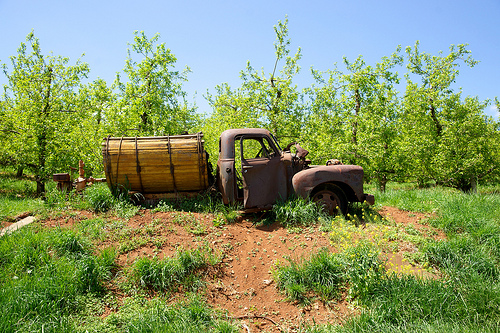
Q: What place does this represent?
A: It represents the field.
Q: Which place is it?
A: It is a field.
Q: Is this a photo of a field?
A: Yes, it is showing a field.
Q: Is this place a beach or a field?
A: It is a field.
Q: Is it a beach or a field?
A: It is a field.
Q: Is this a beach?
A: No, it is a field.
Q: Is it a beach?
A: No, it is a field.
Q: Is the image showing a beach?
A: No, the picture is showing a field.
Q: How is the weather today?
A: It is cloudless.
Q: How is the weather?
A: It is cloudless.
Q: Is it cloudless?
A: Yes, it is cloudless.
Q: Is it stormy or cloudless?
A: It is cloudless.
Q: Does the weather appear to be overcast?
A: No, it is cloudless.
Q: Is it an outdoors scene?
A: Yes, it is outdoors.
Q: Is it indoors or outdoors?
A: It is outdoors.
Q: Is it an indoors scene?
A: No, it is outdoors.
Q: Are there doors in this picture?
A: Yes, there is a door.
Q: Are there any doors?
A: Yes, there is a door.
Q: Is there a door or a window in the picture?
A: Yes, there is a door.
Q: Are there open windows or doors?
A: Yes, there is an open door.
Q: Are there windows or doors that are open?
A: Yes, the door is open.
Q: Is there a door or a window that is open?
A: Yes, the door is open.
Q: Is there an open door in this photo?
A: Yes, there is an open door.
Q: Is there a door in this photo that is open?
A: Yes, there is a door that is open.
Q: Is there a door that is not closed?
A: Yes, there is a open door.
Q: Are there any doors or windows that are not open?
A: No, there is a door but it is open.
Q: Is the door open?
A: Yes, the door is open.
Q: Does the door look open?
A: Yes, the door is open.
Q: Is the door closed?
A: No, the door is open.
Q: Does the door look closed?
A: No, the door is open.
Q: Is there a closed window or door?
A: No, there is a door but it is open.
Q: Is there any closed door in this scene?
A: No, there is a door but it is open.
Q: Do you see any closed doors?
A: No, there is a door but it is open.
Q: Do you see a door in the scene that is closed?
A: No, there is a door but it is open.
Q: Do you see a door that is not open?
A: No, there is a door but it is open.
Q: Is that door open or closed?
A: The door is open.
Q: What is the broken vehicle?
A: The vehicle is a car.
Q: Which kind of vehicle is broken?
A: The vehicle is a car.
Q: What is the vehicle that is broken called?
A: The vehicle is a car.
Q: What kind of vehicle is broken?
A: The vehicle is a car.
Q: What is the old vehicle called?
A: The vehicle is a car.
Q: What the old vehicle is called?
A: The vehicle is a car.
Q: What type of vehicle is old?
A: The vehicle is a car.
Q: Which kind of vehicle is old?
A: The vehicle is a car.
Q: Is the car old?
A: Yes, the car is old.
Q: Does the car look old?
A: Yes, the car is old.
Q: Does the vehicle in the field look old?
A: Yes, the car is old.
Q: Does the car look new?
A: No, the car is old.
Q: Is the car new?
A: No, the car is old.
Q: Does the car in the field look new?
A: No, the car is old.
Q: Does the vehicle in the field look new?
A: No, the car is old.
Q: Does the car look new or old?
A: The car is old.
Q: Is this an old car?
A: Yes, this is an old car.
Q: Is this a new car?
A: No, this is an old car.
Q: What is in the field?
A: The car is in the field.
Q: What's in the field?
A: The car is in the field.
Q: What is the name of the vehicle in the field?
A: The vehicle is a car.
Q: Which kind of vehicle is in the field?
A: The vehicle is a car.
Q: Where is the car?
A: The car is in the field.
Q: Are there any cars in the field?
A: Yes, there is a car in the field.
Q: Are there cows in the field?
A: No, there is a car in the field.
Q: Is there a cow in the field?
A: No, there is a car in the field.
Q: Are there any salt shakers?
A: No, there are no salt shakers.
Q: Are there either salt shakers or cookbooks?
A: No, there are no salt shakers or cookbooks.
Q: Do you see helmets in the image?
A: No, there are no helmets.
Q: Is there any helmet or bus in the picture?
A: No, there are no helmets or buses.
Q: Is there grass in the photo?
A: Yes, there is grass.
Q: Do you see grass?
A: Yes, there is grass.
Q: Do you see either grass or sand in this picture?
A: Yes, there is grass.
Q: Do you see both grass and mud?
A: No, there is grass but no mud.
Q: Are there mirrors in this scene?
A: No, there are no mirrors.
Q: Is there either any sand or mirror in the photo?
A: No, there are no mirrors or sand.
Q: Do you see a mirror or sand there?
A: No, there are no mirrors or sand.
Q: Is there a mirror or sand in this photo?
A: No, there are no mirrors or sand.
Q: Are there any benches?
A: No, there are no benches.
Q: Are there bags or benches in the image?
A: No, there are no benches or bags.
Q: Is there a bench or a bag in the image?
A: No, there are no benches or bags.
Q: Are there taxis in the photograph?
A: Yes, there is a taxi.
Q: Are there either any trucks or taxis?
A: Yes, there is a taxi.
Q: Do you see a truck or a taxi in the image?
A: Yes, there is a taxi.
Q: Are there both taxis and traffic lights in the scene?
A: No, there is a taxi but no traffic lights.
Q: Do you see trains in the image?
A: No, there are no trains.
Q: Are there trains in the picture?
A: No, there are no trains.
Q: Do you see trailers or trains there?
A: No, there are no trains or trailers.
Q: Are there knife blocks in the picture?
A: No, there are no knife blocks.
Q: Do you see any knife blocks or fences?
A: No, there are no knife blocks or fences.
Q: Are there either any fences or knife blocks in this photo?
A: No, there are no knife blocks or fences.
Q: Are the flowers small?
A: Yes, the flowers are small.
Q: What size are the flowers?
A: The flowers are small.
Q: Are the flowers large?
A: No, the flowers are small.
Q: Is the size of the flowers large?
A: No, the flowers are small.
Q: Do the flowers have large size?
A: No, the flowers are small.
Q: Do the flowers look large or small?
A: The flowers are small.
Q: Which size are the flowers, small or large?
A: The flowers are small.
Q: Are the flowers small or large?
A: The flowers are small.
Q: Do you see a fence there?
A: No, there are no fences.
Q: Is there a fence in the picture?
A: No, there are no fences.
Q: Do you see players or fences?
A: No, there are no fences or players.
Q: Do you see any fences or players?
A: No, there are no fences or players.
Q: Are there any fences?
A: No, there are no fences.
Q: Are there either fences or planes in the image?
A: No, there are no fences or planes.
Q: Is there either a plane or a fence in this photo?
A: No, there are no fences or airplanes.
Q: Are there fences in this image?
A: No, there are no fences.